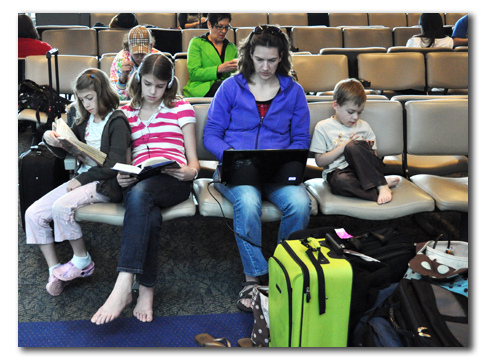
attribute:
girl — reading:
[23, 68, 130, 299]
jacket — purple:
[203, 72, 311, 158]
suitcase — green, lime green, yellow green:
[267, 239, 355, 348]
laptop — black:
[219, 149, 306, 186]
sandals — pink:
[43, 265, 94, 295]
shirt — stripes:
[119, 100, 197, 164]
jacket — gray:
[71, 112, 132, 198]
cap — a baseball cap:
[128, 25, 152, 54]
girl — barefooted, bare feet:
[92, 55, 199, 329]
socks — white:
[71, 254, 92, 266]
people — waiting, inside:
[19, 13, 459, 325]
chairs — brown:
[26, 12, 474, 225]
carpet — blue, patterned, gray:
[17, 213, 294, 350]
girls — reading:
[25, 55, 197, 324]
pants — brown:
[331, 142, 386, 199]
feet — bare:
[90, 268, 154, 325]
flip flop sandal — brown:
[194, 330, 231, 349]